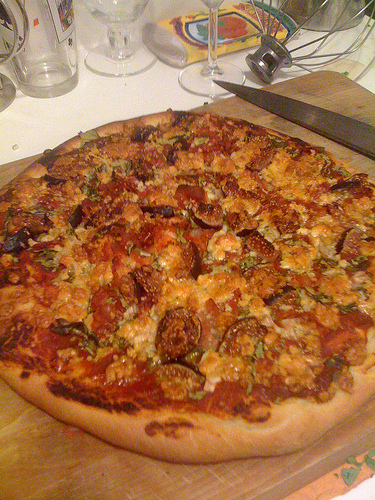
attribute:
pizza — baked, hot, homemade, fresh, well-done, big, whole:
[2, 104, 375, 462]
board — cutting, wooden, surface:
[0, 69, 374, 498]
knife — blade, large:
[213, 75, 374, 159]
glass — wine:
[179, 1, 247, 96]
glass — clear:
[81, 1, 159, 78]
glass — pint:
[5, 3, 81, 100]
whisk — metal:
[243, 1, 374, 83]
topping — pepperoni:
[153, 304, 204, 362]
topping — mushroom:
[245, 147, 282, 170]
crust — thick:
[36, 401, 350, 459]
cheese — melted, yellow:
[165, 270, 241, 304]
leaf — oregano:
[336, 449, 374, 492]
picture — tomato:
[215, 14, 250, 40]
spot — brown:
[146, 418, 198, 441]